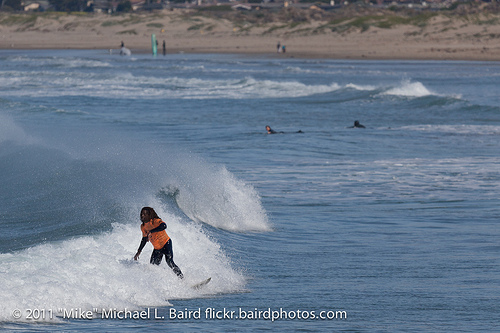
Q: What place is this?
A: It is an ocean.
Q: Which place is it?
A: It is an ocean.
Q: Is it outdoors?
A: Yes, it is outdoors.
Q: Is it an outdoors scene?
A: Yes, it is outdoors.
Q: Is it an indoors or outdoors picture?
A: It is outdoors.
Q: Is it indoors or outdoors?
A: It is outdoors.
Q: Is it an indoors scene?
A: No, it is outdoors.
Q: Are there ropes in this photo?
A: No, there are no ropes.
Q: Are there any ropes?
A: No, there are no ropes.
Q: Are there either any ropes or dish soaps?
A: No, there are no ropes or dish soaps.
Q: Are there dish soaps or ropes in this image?
A: No, there are no ropes or dish soaps.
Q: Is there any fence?
A: No, there are no fences.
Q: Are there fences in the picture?
A: No, there are no fences.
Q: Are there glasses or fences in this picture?
A: No, there are no fences or glasses.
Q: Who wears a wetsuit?
A: The man wears a wetsuit.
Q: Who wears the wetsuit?
A: The man wears a wetsuit.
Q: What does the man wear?
A: The man wears a wetsuit.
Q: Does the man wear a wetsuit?
A: Yes, the man wears a wetsuit.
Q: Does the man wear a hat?
A: No, the man wears a wetsuit.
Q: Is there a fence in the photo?
A: No, there are no fences.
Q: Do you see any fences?
A: No, there are no fences.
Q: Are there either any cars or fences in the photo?
A: No, there are no fences or cars.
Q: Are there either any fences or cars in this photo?
A: No, there are no fences or cars.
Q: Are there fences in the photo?
A: No, there are no fences.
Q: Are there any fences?
A: No, there are no fences.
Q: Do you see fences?
A: No, there are no fences.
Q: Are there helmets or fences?
A: No, there are no fences or helmets.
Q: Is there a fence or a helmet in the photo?
A: No, there are no fences or helmets.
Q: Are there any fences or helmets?
A: No, there are no fences or helmets.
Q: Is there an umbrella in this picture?
A: No, there are no umbrellas.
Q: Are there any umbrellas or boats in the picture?
A: No, there are no umbrellas or boats.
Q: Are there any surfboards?
A: Yes, there is a surfboard.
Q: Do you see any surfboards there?
A: Yes, there is a surfboard.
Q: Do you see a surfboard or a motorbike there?
A: Yes, there is a surfboard.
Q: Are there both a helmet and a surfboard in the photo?
A: No, there is a surfboard but no helmets.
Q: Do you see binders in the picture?
A: No, there are no binders.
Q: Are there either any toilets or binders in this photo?
A: No, there are no binders or toilets.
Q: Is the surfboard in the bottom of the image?
A: Yes, the surfboard is in the bottom of the image.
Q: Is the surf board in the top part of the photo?
A: No, the surf board is in the bottom of the image.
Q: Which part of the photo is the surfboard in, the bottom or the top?
A: The surfboard is in the bottom of the image.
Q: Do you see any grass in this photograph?
A: Yes, there is grass.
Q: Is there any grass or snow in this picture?
A: Yes, there is grass.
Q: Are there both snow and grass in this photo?
A: No, there is grass but no snow.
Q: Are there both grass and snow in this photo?
A: No, there is grass but no snow.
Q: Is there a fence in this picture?
A: No, there are no fences.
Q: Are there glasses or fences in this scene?
A: No, there are no fences or glasses.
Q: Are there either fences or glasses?
A: No, there are no fences or glasses.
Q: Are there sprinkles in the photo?
A: Yes, there are sprinkles.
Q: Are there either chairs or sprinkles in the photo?
A: Yes, there are sprinkles.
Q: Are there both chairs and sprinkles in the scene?
A: No, there are sprinkles but no chairs.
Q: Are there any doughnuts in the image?
A: No, there are no doughnuts.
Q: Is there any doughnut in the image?
A: No, there are no donuts.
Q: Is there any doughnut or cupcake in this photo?
A: No, there are no donuts or cupcakes.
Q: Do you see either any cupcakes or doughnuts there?
A: No, there are no doughnuts or cupcakes.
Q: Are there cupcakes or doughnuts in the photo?
A: No, there are no doughnuts or cupcakes.